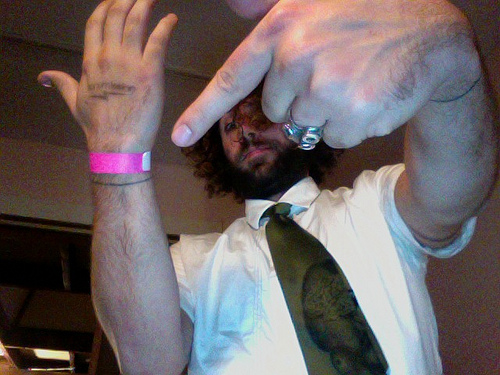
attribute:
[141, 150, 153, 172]
white part —  white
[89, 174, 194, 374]
arm — hairy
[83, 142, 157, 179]
wrist band —  Man's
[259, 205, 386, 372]
tie —  his,  green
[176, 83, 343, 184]
hair —  curly,  his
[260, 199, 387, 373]
green tie —  green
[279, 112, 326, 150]
ring — metal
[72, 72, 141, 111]
stamp —  black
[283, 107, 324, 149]
ring —  silver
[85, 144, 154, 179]
wristband — pink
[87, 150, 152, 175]
pink wristband —  pink,  his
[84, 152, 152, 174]
band —  pink and white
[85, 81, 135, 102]
stamp —  lightning ,  bold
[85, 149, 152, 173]
wrist band — pink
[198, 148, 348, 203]
beard —  large,  his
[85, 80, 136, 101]
tattoo — black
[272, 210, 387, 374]
tie — green 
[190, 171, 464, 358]
shirt — white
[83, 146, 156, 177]
bracelet — pink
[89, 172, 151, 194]
line — black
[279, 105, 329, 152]
ring —  his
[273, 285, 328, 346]
tie — green , black 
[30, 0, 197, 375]
arm — hairy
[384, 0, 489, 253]
arm — hairy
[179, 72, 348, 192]
face —  man's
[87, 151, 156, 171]
band —  pink and white,  wrist's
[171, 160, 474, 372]
shirt — white, button down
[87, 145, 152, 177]
band — pink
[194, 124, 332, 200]
hair — curly, brown